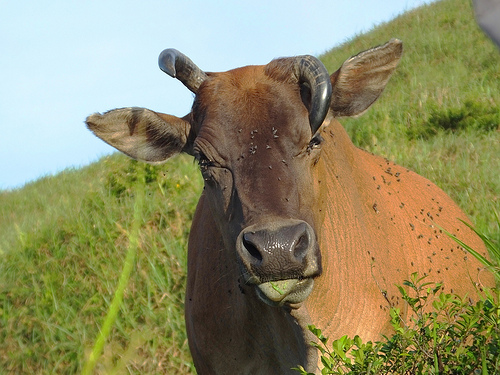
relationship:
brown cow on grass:
[87, 38, 500, 375] [60, 206, 155, 303]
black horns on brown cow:
[157, 48, 209, 92] [87, 38, 500, 375]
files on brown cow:
[228, 99, 288, 175] [87, 38, 500, 375]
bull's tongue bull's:
[190, 124, 359, 317] [256, 277, 303, 302]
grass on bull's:
[268, 285, 284, 298] [256, 277, 303, 302]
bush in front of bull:
[303, 271, 500, 375] [219, 209, 491, 375]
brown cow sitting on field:
[87, 38, 500, 375] [429, 25, 486, 137]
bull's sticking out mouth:
[256, 277, 303, 302] [247, 270, 319, 311]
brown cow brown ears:
[87, 38, 500, 375] [47, 61, 498, 152]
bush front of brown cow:
[303, 271, 500, 375] [87, 38, 500, 375]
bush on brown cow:
[303, 271, 500, 375] [87, 38, 500, 375]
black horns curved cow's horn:
[157, 48, 209, 92] [295, 55, 332, 138]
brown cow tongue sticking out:
[224, 188, 322, 211] [235, 225, 330, 306]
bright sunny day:
[27, 34, 92, 100] [40, 29, 113, 107]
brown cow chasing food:
[224, 188, 322, 211] [267, 289, 312, 306]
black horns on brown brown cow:
[154, 48, 343, 131] [87, 38, 500, 375]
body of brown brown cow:
[338, 155, 464, 307] [87, 38, 500, 375]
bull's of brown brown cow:
[256, 277, 303, 302] [87, 38, 500, 375]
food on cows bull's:
[268, 281, 284, 296] [256, 277, 303, 302]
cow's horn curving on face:
[293, 47, 335, 145] [190, 124, 359, 317]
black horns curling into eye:
[157, 48, 209, 92] [293, 120, 329, 152]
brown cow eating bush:
[87, 38, 500, 375] [390, 298, 458, 374]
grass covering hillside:
[60, 206, 155, 303] [396, 18, 477, 110]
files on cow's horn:
[228, 99, 288, 175] [295, 55, 332, 138]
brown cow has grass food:
[87, 38, 500, 375] [268, 281, 284, 296]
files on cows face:
[228, 99, 288, 175] [210, 115, 312, 182]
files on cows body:
[228, 99, 288, 175] [338, 155, 464, 307]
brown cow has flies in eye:
[87, 38, 500, 375] [187, 145, 228, 174]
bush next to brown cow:
[303, 271, 500, 375] [87, 38, 500, 375]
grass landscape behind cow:
[0, 0, 500, 375] [396, 18, 477, 110]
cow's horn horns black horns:
[295, 55, 332, 138] [157, 48, 209, 92]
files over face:
[228, 99, 288, 175] [210, 115, 312, 182]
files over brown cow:
[228, 99, 288, 175] [87, 38, 500, 375]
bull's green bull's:
[256, 277, 303, 302] [256, 277, 303, 302]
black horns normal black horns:
[157, 48, 209, 92] [157, 48, 209, 92]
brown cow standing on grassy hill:
[87, 38, 500, 375] [437, 16, 472, 131]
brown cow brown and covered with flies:
[87, 38, 500, 375] [338, 155, 464, 307]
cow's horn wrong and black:
[295, 55, 332, 138] [293, 55, 363, 160]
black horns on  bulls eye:
[157, 48, 209, 92] [293, 120, 329, 152]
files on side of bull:
[366, 159, 456, 268] [98, 37, 458, 366]